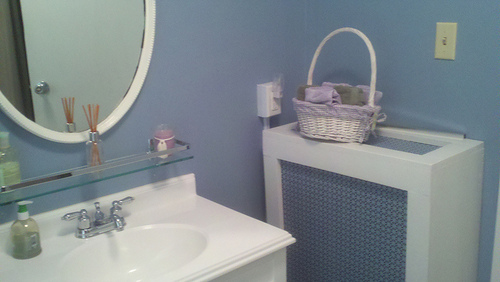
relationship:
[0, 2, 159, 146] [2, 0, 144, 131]
frame on mirror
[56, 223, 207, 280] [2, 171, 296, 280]
sink in counter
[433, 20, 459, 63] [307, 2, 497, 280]
switch on wall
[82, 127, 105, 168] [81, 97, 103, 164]
bottle with incense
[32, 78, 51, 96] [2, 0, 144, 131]
knob in mirror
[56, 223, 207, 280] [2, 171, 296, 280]
sink on counter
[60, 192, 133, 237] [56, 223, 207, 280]
faucet on sink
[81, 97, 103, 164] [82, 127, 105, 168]
incense in bottle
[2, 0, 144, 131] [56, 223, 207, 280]
mirror above sink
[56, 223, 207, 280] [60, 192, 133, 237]
sink by faucet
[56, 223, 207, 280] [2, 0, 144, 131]
sink under mirror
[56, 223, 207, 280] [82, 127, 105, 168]
sink by bottle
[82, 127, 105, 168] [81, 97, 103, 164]
bottle of incense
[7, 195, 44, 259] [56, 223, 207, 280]
soap by sink